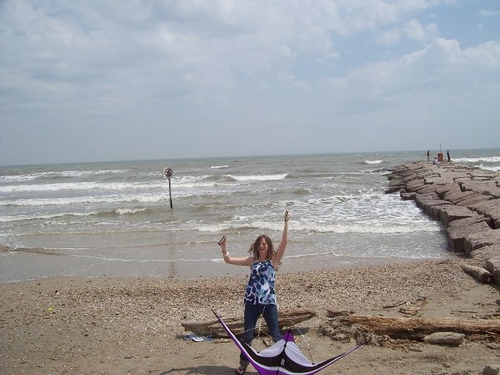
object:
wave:
[0, 155, 499, 262]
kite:
[209, 308, 373, 374]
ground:
[0, 256, 499, 375]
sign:
[162, 166, 174, 178]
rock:
[444, 221, 494, 248]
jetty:
[380, 160, 499, 291]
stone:
[460, 181, 491, 194]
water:
[0, 149, 499, 284]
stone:
[402, 177, 426, 192]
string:
[257, 328, 279, 343]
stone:
[452, 194, 493, 208]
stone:
[460, 228, 499, 256]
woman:
[218, 210, 289, 374]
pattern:
[243, 258, 278, 306]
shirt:
[242, 256, 276, 308]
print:
[240, 255, 280, 305]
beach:
[0, 259, 499, 374]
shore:
[0, 232, 499, 375]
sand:
[0, 263, 499, 375]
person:
[444, 149, 452, 163]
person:
[422, 150, 432, 162]